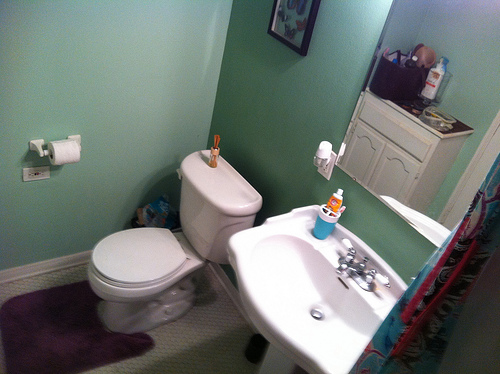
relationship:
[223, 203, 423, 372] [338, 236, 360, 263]
sink has faucet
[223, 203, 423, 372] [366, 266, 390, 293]
sink has faucet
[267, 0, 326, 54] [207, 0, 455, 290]
framed art on wall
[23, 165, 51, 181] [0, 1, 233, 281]
electrical outlet in wall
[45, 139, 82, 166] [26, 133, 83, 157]
tissuepaper on paper holder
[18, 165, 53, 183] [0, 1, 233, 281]
electrical outlet on wall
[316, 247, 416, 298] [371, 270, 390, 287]
faucet with handle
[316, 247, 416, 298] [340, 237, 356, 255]
faucet with handle